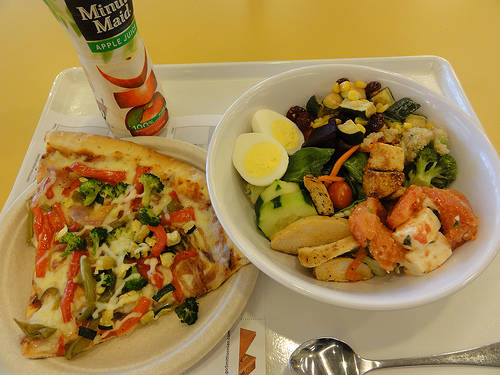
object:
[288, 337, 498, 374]
spoon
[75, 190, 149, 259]
toppings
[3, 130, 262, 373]
plate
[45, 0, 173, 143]
bottle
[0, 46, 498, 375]
tray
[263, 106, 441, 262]
salad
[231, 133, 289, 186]
eggs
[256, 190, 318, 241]
cucumber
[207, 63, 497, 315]
plate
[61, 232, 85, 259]
broccoli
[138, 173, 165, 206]
broccoli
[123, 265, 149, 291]
broccoli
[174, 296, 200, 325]
broccoli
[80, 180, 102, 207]
broccoli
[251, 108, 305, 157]
egg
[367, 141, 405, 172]
crouton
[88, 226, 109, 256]
broccoli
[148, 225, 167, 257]
peppers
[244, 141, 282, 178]
yolk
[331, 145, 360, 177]
carrots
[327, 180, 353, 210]
tomato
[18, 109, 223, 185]
paper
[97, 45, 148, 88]
apples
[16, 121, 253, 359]
food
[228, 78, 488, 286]
food